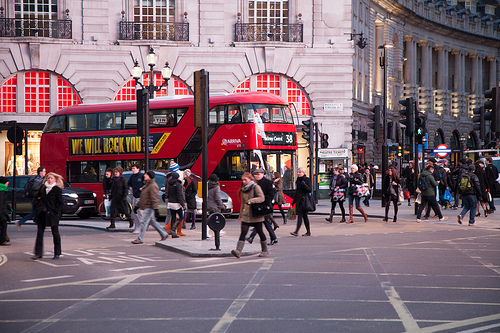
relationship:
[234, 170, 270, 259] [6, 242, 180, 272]
woman walking across crosswalk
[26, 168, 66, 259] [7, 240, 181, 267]
woman walking across crosswalk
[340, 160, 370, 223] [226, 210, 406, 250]
woman walking across crosswalk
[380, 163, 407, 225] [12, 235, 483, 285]
woman walking across crosswalk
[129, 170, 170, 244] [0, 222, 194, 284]
man walking across crosswalk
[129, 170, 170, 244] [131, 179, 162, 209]
man wearing jacket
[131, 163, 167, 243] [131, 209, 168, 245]
man wearing jeans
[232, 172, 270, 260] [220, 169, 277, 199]
woman wearing scarf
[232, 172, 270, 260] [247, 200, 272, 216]
woman with purse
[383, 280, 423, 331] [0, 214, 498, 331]
white stripe in street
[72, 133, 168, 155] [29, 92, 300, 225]
sign on bus